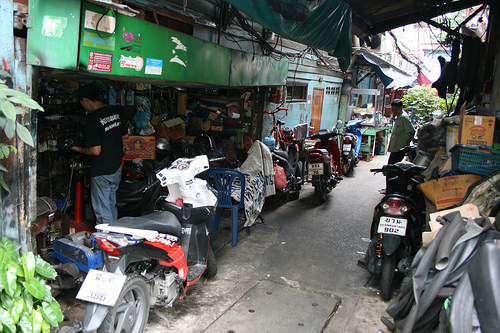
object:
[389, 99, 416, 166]
man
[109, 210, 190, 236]
seat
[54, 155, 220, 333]
scooter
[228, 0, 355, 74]
green tarp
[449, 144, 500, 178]
plastic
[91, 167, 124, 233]
jeans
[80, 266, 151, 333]
license plate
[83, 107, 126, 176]
shirt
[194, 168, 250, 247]
blue chair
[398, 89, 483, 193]
table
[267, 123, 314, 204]
bicycle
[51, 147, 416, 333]
cement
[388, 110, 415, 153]
shirt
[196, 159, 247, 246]
giraffe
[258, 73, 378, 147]
wall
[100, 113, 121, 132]
writing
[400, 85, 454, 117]
green leaves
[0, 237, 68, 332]
tree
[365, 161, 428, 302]
motorcycle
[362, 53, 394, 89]
tarp canopy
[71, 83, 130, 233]
man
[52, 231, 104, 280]
hamper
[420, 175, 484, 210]
box